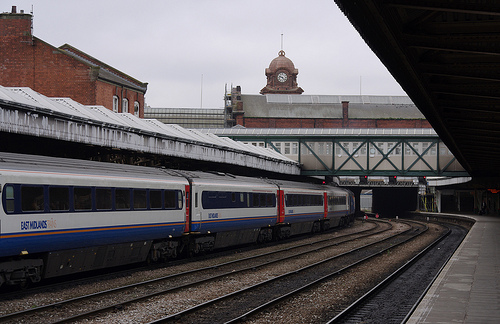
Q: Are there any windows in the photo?
A: Yes, there is a window.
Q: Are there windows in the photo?
A: Yes, there is a window.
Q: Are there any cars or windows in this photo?
A: Yes, there is a window.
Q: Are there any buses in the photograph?
A: No, there are no buses.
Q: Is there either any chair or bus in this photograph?
A: No, there are no buses or chairs.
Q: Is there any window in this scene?
A: Yes, there is a window.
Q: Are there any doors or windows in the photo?
A: Yes, there is a window.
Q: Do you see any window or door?
A: Yes, there is a window.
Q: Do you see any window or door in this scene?
A: Yes, there is a window.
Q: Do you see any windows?
A: Yes, there is a window.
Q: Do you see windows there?
A: Yes, there is a window.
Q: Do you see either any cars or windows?
A: Yes, there is a window.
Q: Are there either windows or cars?
A: Yes, there is a window.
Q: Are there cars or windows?
A: Yes, there is a window.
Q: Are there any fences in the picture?
A: No, there are no fences.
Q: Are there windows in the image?
A: Yes, there is a window.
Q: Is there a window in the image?
A: Yes, there is a window.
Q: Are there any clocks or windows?
A: Yes, there is a window.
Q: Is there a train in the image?
A: Yes, there is a train.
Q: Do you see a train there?
A: Yes, there is a train.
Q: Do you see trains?
A: Yes, there is a train.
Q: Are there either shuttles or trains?
A: Yes, there is a train.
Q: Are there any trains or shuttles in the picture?
A: Yes, there is a train.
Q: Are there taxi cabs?
A: No, there are no taxi cabs.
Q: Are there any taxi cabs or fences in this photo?
A: No, there are no taxi cabs or fences.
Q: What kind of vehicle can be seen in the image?
A: The vehicle is a train.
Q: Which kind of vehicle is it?
A: The vehicle is a train.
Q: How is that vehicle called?
A: This is a train.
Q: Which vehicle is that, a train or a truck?
A: This is a train.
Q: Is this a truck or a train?
A: This is a train.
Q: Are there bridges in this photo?
A: Yes, there is a bridge.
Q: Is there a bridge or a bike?
A: Yes, there is a bridge.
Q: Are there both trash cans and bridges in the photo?
A: No, there is a bridge but no trash cans.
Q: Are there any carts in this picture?
A: No, there are no carts.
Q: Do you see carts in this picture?
A: No, there are no carts.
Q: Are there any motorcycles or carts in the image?
A: No, there are no carts or motorcycles.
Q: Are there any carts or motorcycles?
A: No, there are no carts or motorcycles.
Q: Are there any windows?
A: Yes, there is a window.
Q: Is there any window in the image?
A: Yes, there is a window.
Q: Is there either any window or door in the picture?
A: Yes, there is a window.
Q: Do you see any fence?
A: No, there are no fences.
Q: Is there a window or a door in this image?
A: Yes, there is a window.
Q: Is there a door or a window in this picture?
A: Yes, there is a window.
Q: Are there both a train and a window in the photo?
A: Yes, there are both a window and a train.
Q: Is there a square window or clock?
A: Yes, there is a square window.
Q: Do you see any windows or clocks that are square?
A: Yes, the window is square.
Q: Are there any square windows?
A: Yes, there is a square window.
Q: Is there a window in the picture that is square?
A: Yes, there is a window that is square.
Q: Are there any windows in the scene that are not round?
A: Yes, there is a square window.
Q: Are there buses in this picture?
A: No, there are no buses.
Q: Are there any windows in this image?
A: Yes, there is a window.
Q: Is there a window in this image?
A: Yes, there is a window.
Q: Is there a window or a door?
A: Yes, there is a window.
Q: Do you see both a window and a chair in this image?
A: No, there is a window but no chairs.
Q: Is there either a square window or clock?
A: Yes, there is a square window.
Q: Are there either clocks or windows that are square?
A: Yes, the window is square.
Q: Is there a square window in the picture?
A: Yes, there is a square window.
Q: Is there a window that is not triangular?
A: Yes, there is a square window.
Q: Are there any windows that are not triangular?
A: Yes, there is a square window.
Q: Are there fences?
A: No, there are no fences.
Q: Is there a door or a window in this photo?
A: Yes, there is a window.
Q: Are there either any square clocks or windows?
A: Yes, there is a square window.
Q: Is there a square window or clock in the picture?
A: Yes, there is a square window.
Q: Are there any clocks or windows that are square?
A: Yes, the window is square.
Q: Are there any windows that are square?
A: Yes, there is a square window.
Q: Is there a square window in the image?
A: Yes, there is a square window.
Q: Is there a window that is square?
A: Yes, there is a window that is square.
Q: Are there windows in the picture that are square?
A: Yes, there is a window that is square.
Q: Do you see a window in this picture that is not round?
A: Yes, there is a square window.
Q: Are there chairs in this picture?
A: No, there are no chairs.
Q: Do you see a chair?
A: No, there are no chairs.